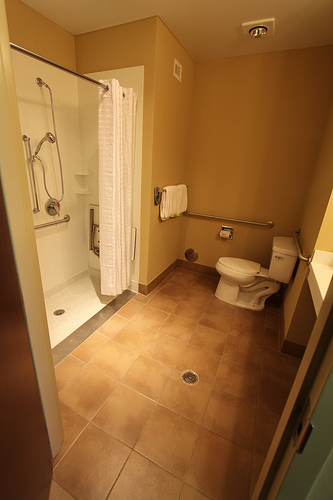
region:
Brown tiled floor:
[98, 346, 173, 420]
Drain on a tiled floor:
[170, 363, 210, 400]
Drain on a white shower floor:
[46, 301, 75, 326]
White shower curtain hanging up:
[88, 82, 149, 312]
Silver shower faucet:
[22, 77, 77, 212]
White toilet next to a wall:
[210, 222, 331, 326]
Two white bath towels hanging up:
[154, 182, 195, 227]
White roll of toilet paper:
[214, 222, 233, 239]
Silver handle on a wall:
[196, 199, 269, 236]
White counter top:
[299, 243, 331, 290]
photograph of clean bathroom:
[12, 0, 327, 493]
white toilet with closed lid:
[205, 229, 302, 316]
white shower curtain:
[91, 77, 141, 302]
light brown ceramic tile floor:
[108, 317, 245, 477]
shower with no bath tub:
[41, 57, 139, 364]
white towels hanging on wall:
[150, 168, 201, 230]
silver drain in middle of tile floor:
[158, 357, 212, 406]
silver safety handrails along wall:
[179, 217, 288, 227]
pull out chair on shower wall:
[81, 196, 120, 268]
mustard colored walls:
[141, 87, 200, 178]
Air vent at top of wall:
[168, 55, 195, 83]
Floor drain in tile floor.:
[174, 363, 203, 395]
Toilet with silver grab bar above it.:
[204, 225, 310, 315]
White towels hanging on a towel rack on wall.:
[152, 179, 191, 229]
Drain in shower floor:
[48, 304, 71, 321]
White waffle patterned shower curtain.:
[89, 75, 146, 304]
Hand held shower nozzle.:
[35, 124, 67, 207]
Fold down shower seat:
[81, 196, 102, 263]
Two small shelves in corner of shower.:
[72, 159, 95, 204]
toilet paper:
[213, 228, 241, 241]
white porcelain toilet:
[207, 232, 300, 317]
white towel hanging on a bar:
[152, 174, 191, 227]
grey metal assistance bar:
[181, 206, 277, 230]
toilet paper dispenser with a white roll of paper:
[215, 223, 235, 243]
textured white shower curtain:
[84, 69, 143, 301]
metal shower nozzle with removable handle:
[17, 71, 70, 214]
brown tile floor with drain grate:
[141, 331, 237, 417]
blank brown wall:
[199, 100, 304, 182]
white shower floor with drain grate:
[39, 276, 112, 321]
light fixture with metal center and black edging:
[234, 16, 283, 46]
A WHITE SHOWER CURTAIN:
[92, 75, 143, 300]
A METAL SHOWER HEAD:
[33, 127, 61, 155]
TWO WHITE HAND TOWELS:
[154, 178, 193, 220]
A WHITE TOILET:
[210, 252, 279, 312]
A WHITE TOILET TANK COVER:
[267, 230, 301, 258]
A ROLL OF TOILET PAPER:
[214, 221, 237, 239]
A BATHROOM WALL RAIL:
[180, 204, 285, 232]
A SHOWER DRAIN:
[47, 303, 73, 319]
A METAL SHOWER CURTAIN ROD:
[6, 37, 138, 95]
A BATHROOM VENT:
[162, 50, 194, 87]